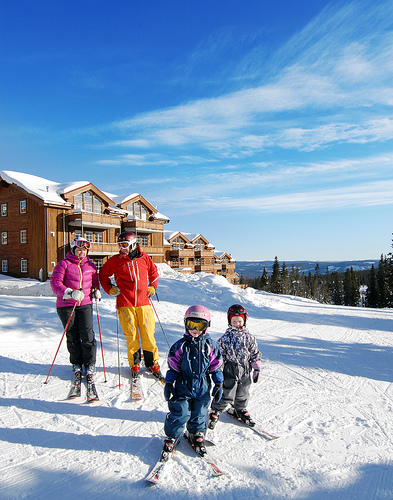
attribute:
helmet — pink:
[68, 234, 89, 254]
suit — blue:
[159, 329, 239, 458]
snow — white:
[1, 262, 391, 498]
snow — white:
[2, 165, 90, 209]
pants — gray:
[221, 364, 252, 413]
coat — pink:
[51, 256, 104, 312]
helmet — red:
[225, 303, 248, 324]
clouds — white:
[112, 68, 369, 206]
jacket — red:
[215, 325, 262, 365]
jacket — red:
[97, 242, 159, 305]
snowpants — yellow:
[117, 298, 165, 378]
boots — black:
[158, 426, 219, 466]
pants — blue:
[167, 379, 217, 426]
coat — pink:
[46, 250, 104, 314]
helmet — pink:
[180, 298, 214, 337]